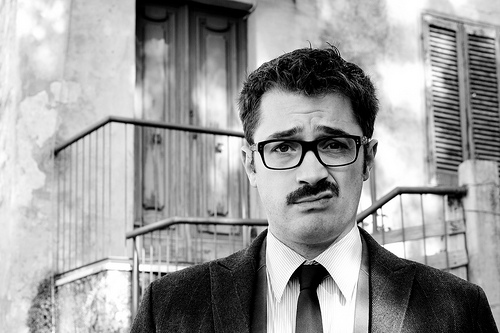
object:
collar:
[267, 222, 362, 307]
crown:
[128, 227, 500, 333]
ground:
[433, 125, 465, 173]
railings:
[55, 116, 245, 154]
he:
[133, 48, 500, 333]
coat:
[129, 225, 500, 333]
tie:
[291, 264, 329, 333]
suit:
[134, 229, 500, 332]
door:
[138, 0, 249, 265]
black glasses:
[249, 133, 368, 170]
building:
[13, 0, 497, 333]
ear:
[240, 146, 257, 188]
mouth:
[289, 192, 332, 209]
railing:
[126, 187, 467, 238]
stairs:
[381, 198, 470, 278]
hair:
[237, 40, 380, 173]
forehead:
[252, 89, 365, 137]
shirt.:
[254, 218, 369, 333]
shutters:
[423, 10, 500, 186]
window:
[422, 8, 500, 184]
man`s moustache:
[286, 180, 339, 205]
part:
[44, 58, 98, 99]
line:
[289, 110, 322, 115]